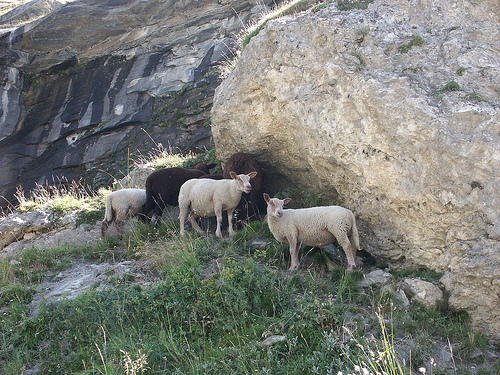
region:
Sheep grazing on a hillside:
[77, 148, 388, 276]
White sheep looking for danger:
[250, 186, 365, 283]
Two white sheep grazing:
[172, 166, 372, 276]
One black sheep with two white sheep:
[95, 157, 230, 237]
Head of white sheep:
[255, 187, 295, 222]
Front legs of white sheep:
[207, 195, 242, 240]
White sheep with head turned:
[255, 186, 365, 286]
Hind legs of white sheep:
[320, 231, 356, 281]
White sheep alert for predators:
[255, 190, 375, 280]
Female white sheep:
[255, 187, 370, 280]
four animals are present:
[89, 151, 385, 314]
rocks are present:
[29, 215, 140, 350]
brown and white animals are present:
[136, 111, 448, 310]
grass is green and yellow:
[139, 243, 262, 320]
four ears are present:
[206, 166, 331, 265]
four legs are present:
[173, 199, 240, 246]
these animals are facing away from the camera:
[115, 151, 190, 226]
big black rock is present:
[47, 26, 152, 127]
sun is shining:
[210, 8, 291, 70]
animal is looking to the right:
[264, 190, 406, 343]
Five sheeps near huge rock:
[90, 155, 372, 273]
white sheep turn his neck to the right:
[246, 185, 361, 280]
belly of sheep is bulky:
[185, 195, 211, 220]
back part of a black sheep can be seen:
[140, 161, 180, 226]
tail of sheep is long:
[346, 210, 366, 255]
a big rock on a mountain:
[207, 5, 492, 165]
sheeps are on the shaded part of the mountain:
[85, 5, 496, 280]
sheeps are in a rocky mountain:
[5, 31, 495, 366]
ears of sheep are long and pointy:
[255, 190, 290, 205]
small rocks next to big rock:
[364, 263, 443, 325]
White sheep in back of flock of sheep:
[95, 180, 148, 240]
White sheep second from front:
[175, 165, 260, 235]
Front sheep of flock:
[257, 193, 367, 278]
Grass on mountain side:
[5, 227, 490, 367]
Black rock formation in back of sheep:
[1, 65, 216, 211]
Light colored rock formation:
[211, 65, 496, 331]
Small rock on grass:
[356, 265, 446, 316]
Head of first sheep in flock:
[256, 188, 294, 219]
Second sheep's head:
[222, 163, 260, 194]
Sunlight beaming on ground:
[0, 127, 215, 239]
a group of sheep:
[70, 145, 391, 278]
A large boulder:
[236, 20, 497, 252]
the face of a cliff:
[1, 4, 223, 168]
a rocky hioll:
[1, 180, 471, 374]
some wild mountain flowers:
[87, 317, 456, 374]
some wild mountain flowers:
[7, 157, 101, 222]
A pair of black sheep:
[147, 155, 288, 209]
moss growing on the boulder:
[375, 27, 481, 92]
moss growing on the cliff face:
[101, 72, 209, 154]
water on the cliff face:
[1, 20, 132, 187]